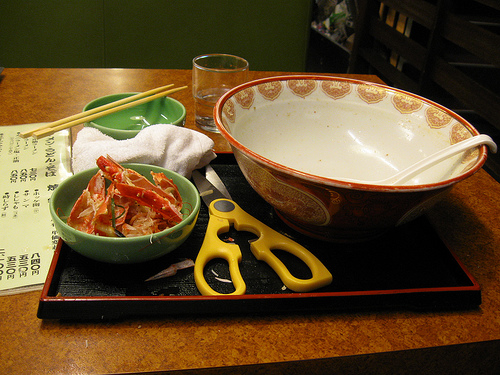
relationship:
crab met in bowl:
[69, 156, 183, 236] [50, 162, 201, 261]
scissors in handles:
[168, 154, 343, 295] [197, 220, 336, 291]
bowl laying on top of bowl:
[81, 92, 186, 140] [84, 89, 189, 138]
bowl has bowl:
[215, 70, 498, 242] [212, 74, 488, 239]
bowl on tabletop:
[223, 72, 497, 218] [0, 67, 492, 372]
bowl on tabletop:
[49, 154, 199, 260] [0, 67, 492, 372]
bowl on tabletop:
[90, 82, 197, 146] [0, 67, 492, 372]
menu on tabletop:
[1, 119, 73, 292] [0, 67, 492, 372]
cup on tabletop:
[190, 53, 249, 133] [0, 67, 492, 372]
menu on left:
[0, 122, 74, 295] [4, 15, 58, 369]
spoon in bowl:
[333, 134, 496, 185] [212, 74, 486, 216]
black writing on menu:
[21, 250, 43, 279] [6, 188, 51, 280]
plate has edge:
[37, 151, 481, 319] [39, 288, 353, 308]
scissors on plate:
[191, 164, 333, 296] [53, 249, 478, 309]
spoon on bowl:
[382, 132, 498, 177] [195, 69, 495, 251]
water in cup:
[193, 87, 233, 129] [194, 50, 246, 132]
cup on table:
[194, 50, 246, 132] [0, 62, 499, 369]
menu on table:
[0, 122, 74, 295] [8, 65, 96, 120]